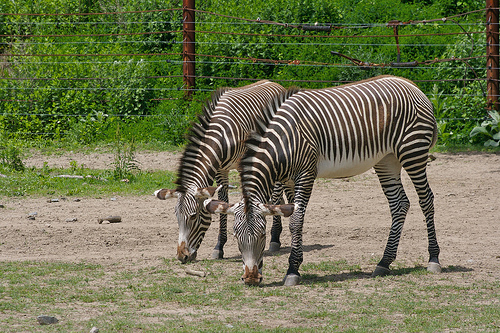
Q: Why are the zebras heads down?
A: They're grazing.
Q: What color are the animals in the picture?
A: Black and white.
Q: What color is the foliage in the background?
A: Green.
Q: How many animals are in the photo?
A: Two.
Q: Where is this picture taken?
A: By animals and a fence.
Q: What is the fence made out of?
A: Electric wire.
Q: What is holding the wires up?
A: Wooden posts.